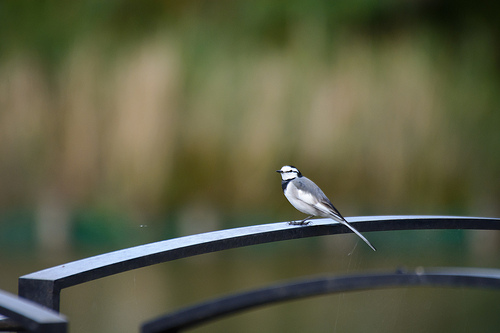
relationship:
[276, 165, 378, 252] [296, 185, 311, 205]
bird with feathers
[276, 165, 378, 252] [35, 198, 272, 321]
bird on rail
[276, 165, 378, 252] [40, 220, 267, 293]
bird on rail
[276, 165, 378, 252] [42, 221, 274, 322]
bird on rail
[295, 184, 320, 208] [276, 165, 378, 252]
feathers on bird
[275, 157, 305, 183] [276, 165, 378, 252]
head of bird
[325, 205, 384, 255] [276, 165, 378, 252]
tail of bird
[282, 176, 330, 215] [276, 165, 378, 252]
body of bird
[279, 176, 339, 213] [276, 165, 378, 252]
body of bird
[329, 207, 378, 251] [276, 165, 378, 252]
tail of bird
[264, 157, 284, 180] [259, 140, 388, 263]
peck of bird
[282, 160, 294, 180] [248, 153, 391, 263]
eye of bird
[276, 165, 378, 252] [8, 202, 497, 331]
bird on metal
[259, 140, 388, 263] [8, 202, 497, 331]
bird on metal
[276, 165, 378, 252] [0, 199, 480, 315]
bird on piece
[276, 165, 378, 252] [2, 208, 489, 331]
bird standing on fence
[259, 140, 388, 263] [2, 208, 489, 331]
bird standing on fence